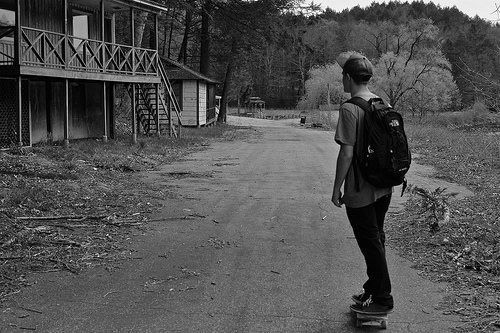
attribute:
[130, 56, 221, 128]
shed — white, wooden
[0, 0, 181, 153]
house — cabin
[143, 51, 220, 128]
house — cabin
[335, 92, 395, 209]
shirt — grey 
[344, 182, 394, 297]
pants — dark 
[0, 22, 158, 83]
porch — railed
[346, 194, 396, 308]
pants — long, black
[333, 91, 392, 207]
shirt — light, short sleeve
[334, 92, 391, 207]
t-shirt — short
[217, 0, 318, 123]
tree — small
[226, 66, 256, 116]
tree — small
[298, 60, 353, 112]
tree — small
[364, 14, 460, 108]
tree — large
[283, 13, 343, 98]
tree — large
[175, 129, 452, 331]
path — dirt